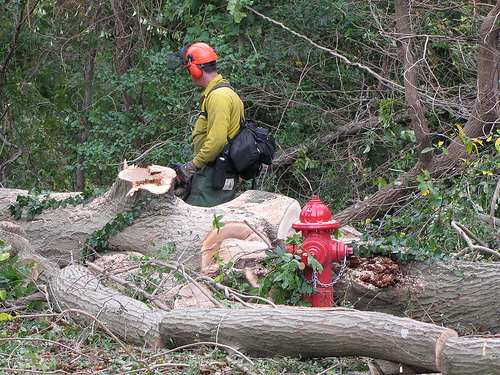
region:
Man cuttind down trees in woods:
[160, 23, 273, 210]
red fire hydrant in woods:
[290, 184, 350, 292]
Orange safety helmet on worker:
[178, 44, 228, 79]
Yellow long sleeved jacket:
[185, 76, 269, 188]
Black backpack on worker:
[226, 105, 284, 181]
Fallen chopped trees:
[3, 155, 443, 341]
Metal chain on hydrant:
[303, 251, 377, 306]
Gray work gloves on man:
[159, 155, 202, 177]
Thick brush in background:
[48, 14, 495, 191]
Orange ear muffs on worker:
[169, 53, 210, 85]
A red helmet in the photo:
[176, 42, 216, 72]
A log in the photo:
[152, 296, 422, 358]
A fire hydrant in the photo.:
[282, 194, 349, 301]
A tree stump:
[105, 151, 174, 218]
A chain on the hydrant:
[309, 259, 353, 299]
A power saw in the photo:
[169, 157, 194, 198]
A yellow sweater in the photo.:
[190, 77, 244, 162]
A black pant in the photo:
[187, 154, 235, 209]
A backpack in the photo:
[222, 127, 272, 177]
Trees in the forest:
[304, 5, 491, 190]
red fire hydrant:
[295, 199, 348, 312]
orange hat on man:
[182, 43, 214, 79]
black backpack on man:
[226, 119, 272, 185]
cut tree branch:
[116, 158, 188, 201]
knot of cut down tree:
[336, 235, 413, 291]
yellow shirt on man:
[187, 77, 245, 169]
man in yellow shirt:
[176, 40, 263, 215]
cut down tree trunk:
[12, 162, 497, 341]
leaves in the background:
[88, 55, 163, 130]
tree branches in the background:
[394, 78, 468, 168]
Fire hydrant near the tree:
[279, 195, 361, 299]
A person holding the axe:
[161, 150, 193, 200]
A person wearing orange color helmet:
[176, 43, 225, 73]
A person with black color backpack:
[201, 85, 291, 182]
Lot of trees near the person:
[14, 0, 472, 42]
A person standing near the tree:
[153, 38, 257, 190]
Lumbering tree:
[59, 173, 264, 332]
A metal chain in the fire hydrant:
[309, 258, 358, 290]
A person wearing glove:
[178, 160, 198, 185]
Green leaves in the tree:
[71, 54, 164, 138]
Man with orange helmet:
[180, 45, 219, 77]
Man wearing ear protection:
[183, 48, 208, 86]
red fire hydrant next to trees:
[274, 188, 373, 309]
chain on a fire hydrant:
[299, 257, 366, 289]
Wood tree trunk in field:
[77, 130, 456, 374]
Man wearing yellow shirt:
[191, 80, 247, 177]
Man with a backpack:
[222, 107, 279, 174]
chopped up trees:
[130, 158, 317, 314]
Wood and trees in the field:
[78, 97, 380, 328]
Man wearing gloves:
[164, 149, 222, 189]